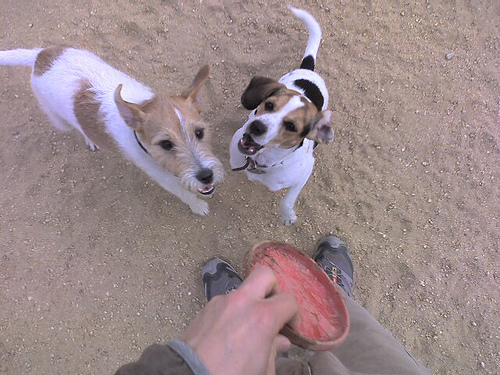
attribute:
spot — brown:
[74, 78, 124, 160]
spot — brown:
[33, 45, 74, 77]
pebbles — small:
[34, 187, 170, 300]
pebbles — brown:
[10, 164, 167, 329]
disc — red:
[233, 230, 355, 350]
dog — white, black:
[228, 2, 333, 227]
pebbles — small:
[382, 35, 476, 118]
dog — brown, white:
[0, 39, 222, 215]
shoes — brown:
[303, 232, 363, 287]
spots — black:
[295, 49, 336, 113]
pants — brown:
[275, 282, 425, 374]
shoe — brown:
[198, 252, 244, 302]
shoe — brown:
[308, 234, 357, 298]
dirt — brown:
[360, 45, 487, 297]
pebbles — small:
[441, 52, 453, 61]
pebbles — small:
[377, 220, 390, 247]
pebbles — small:
[82, 247, 122, 303]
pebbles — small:
[40, 250, 122, 295]